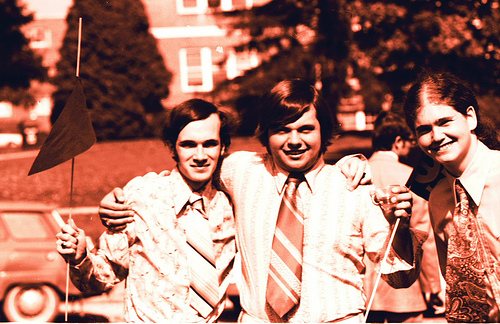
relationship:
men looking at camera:
[68, 87, 236, 323] [53, 77, 499, 317]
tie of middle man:
[258, 174, 316, 321] [216, 70, 395, 322]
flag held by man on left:
[49, 37, 100, 319] [68, 87, 236, 323]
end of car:
[30, 194, 115, 299] [2, 195, 126, 315]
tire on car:
[3, 271, 62, 319] [2, 195, 126, 315]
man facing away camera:
[361, 106, 413, 169] [53, 77, 499, 317]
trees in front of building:
[4, 0, 190, 128] [0, 2, 433, 103]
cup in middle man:
[368, 166, 408, 222] [361, 106, 413, 169]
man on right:
[398, 64, 499, 306] [355, 15, 495, 322]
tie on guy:
[145, 184, 233, 306] [68, 87, 236, 323]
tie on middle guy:
[258, 174, 316, 321] [216, 70, 395, 322]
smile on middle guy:
[274, 135, 315, 166] [216, 70, 395, 322]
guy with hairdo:
[398, 64, 499, 306] [405, 60, 472, 106]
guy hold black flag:
[216, 70, 395, 322] [372, 174, 438, 272]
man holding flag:
[398, 64, 499, 306] [49, 37, 100, 319]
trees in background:
[4, 0, 190, 128] [11, 14, 496, 170]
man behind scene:
[361, 106, 413, 169] [53, 77, 499, 317]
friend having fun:
[68, 87, 236, 323] [53, 77, 499, 317]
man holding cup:
[216, 70, 395, 322] [368, 166, 408, 222]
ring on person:
[387, 183, 413, 195] [361, 106, 413, 169]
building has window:
[0, 2, 433, 103] [172, 41, 222, 102]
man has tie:
[398, 64, 499, 306] [435, 178, 496, 319]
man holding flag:
[361, 106, 413, 169] [49, 37, 100, 319]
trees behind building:
[4, 0, 190, 128] [0, 2, 433, 103]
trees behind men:
[4, 0, 190, 128] [68, 87, 236, 323]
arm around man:
[86, 174, 156, 238] [68, 87, 236, 323]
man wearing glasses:
[361, 106, 413, 169] [402, 126, 423, 149]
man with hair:
[361, 106, 413, 169] [161, 106, 210, 130]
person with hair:
[361, 106, 413, 169] [360, 100, 409, 148]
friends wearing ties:
[53, 77, 499, 317] [258, 174, 316, 321]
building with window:
[0, 2, 433, 103] [172, 41, 222, 102]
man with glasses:
[361, 106, 413, 169] [402, 126, 423, 149]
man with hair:
[361, 106, 413, 169] [360, 100, 409, 148]